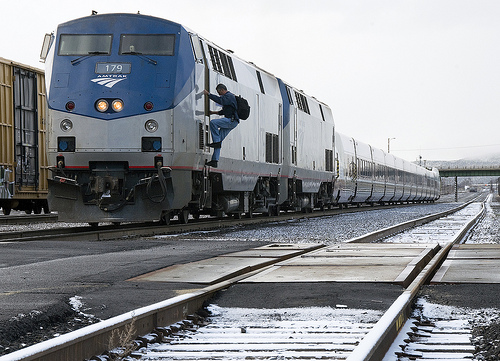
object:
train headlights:
[97, 99, 124, 113]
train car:
[333, 133, 356, 205]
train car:
[351, 138, 372, 205]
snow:
[206, 307, 353, 358]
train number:
[95, 61, 132, 74]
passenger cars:
[334, 131, 440, 208]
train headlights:
[60, 100, 159, 132]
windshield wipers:
[70, 51, 157, 65]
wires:
[146, 162, 167, 203]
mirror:
[39, 32, 54, 63]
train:
[38, 11, 440, 228]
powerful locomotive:
[39, 10, 337, 226]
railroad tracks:
[68, 204, 368, 361]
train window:
[118, 31, 174, 56]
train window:
[58, 34, 113, 57]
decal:
[91, 74, 128, 88]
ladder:
[203, 63, 210, 207]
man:
[203, 83, 238, 168]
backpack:
[235, 95, 250, 120]